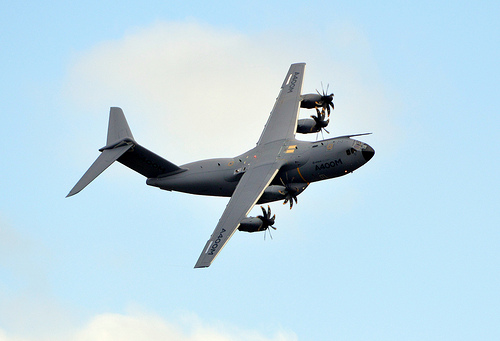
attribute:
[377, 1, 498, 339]
sky — blue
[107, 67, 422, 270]
airplane — identifying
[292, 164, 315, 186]
stripe — color yellow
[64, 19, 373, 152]
clouds — white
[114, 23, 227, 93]
clouds — white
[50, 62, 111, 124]
clouds — white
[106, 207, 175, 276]
clouds — white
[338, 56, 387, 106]
clouds — white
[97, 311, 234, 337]
clouds — white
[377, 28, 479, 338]
sky — part, light blue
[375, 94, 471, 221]
sky — blue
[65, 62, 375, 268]
plane — black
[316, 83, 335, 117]
propeller — color black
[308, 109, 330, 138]
propeller — color black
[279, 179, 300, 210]
propeller — color black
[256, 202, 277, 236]
propeller — color black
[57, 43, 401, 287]
plane — air, dull grey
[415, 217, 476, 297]
blue sky — part, light blue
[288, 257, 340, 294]
sky — blue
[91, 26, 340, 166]
clouds — white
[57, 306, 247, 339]
clouds — white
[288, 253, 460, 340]
sky — part, light blue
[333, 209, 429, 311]
sky — part, light blue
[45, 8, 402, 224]
clouds — white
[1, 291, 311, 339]
clouds — white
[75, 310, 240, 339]
cloud — white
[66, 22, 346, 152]
cloud — white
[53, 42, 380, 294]
airplane — gray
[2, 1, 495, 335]
sky — blue, part, light blue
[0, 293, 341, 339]
clouds — white